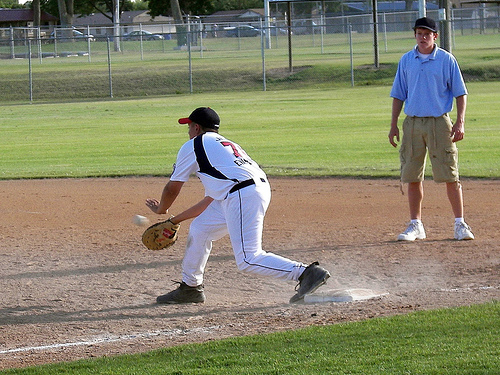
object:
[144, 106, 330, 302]
player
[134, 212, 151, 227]
ball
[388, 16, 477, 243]
coach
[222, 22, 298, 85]
fence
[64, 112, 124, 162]
field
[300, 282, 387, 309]
mound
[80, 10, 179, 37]
houses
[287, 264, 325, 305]
shoes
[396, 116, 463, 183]
shorts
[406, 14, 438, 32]
hat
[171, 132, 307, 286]
uniform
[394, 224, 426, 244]
shoes